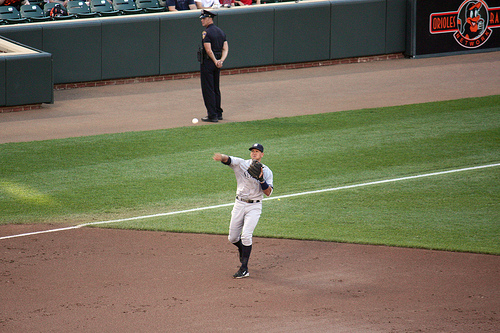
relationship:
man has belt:
[209, 144, 272, 277] [231, 193, 303, 218]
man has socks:
[209, 141, 279, 282] [229, 240, 254, 270]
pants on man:
[222, 194, 267, 249] [214, 137, 277, 284]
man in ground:
[194, 9, 229, 121] [1, 51, 499, 332]